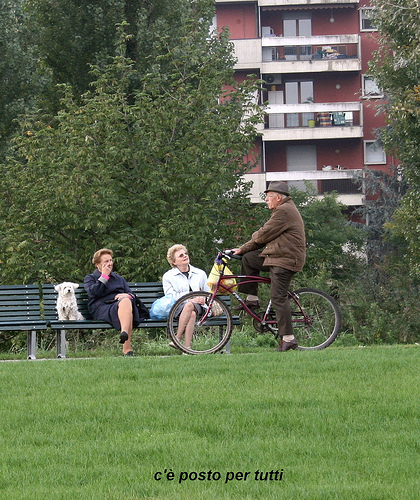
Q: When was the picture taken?
A: Daytime.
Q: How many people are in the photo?
A: Three.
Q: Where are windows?
A: On a building.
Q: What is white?
A: A dog.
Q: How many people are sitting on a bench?
A: Two.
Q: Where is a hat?
A: On a man's head.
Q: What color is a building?
A: Red.